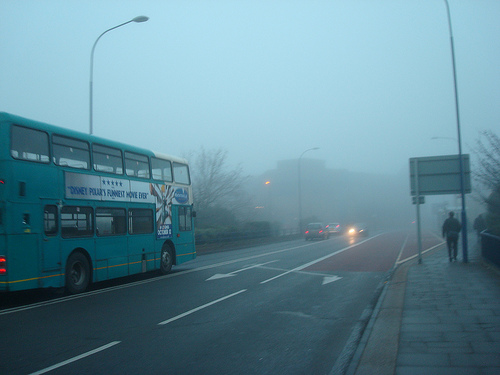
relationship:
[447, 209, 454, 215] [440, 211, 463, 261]
goggles on man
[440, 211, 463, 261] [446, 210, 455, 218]
man on head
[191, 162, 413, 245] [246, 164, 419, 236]
building on a corner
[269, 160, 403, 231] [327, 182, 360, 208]
building on a corner